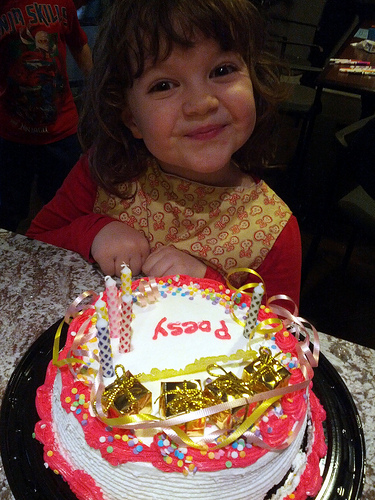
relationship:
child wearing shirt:
[2, 1, 96, 235] [1, 3, 88, 147]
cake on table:
[31, 274, 330, 499] [0, 225, 372, 498]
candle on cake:
[242, 275, 266, 340] [31, 274, 330, 499]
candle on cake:
[119, 290, 134, 350] [31, 274, 330, 499]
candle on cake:
[116, 261, 132, 299] [31, 274, 330, 499]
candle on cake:
[101, 271, 119, 337] [31, 274, 330, 499]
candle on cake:
[95, 316, 113, 378] [31, 274, 330, 499]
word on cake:
[151, 314, 233, 346] [31, 274, 330, 499]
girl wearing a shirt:
[25, 5, 300, 313] [1, 3, 88, 147]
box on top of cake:
[244, 351, 284, 403] [31, 274, 330, 499]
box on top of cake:
[207, 371, 248, 437] [31, 274, 330, 499]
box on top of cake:
[161, 379, 201, 431] [31, 274, 330, 499]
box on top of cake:
[94, 368, 149, 415] [31, 274, 330, 499]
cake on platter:
[31, 274, 330, 499] [1, 318, 368, 499]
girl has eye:
[25, 5, 300, 313] [146, 77, 182, 95]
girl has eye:
[25, 5, 300, 313] [206, 60, 238, 79]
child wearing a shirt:
[2, 1, 96, 235] [1, 3, 88, 147]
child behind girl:
[2, 1, 96, 235] [25, 5, 300, 313]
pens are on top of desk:
[329, 56, 374, 77] [317, 0, 375, 126]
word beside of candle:
[151, 314, 233, 346] [242, 275, 266, 340]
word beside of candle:
[151, 314, 233, 346] [116, 261, 132, 299]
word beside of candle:
[151, 314, 233, 346] [119, 290, 134, 350]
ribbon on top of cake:
[263, 293, 327, 371] [31, 274, 330, 499]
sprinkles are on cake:
[130, 287, 247, 315] [31, 274, 330, 499]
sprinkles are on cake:
[60, 382, 289, 473] [31, 274, 330, 499]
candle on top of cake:
[95, 316, 113, 378] [31, 274, 330, 499]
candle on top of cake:
[119, 290, 134, 350] [31, 274, 330, 499]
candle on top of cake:
[101, 271, 119, 337] [31, 274, 330, 499]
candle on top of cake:
[116, 261, 132, 299] [31, 274, 330, 499]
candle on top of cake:
[242, 275, 266, 340] [31, 274, 330, 499]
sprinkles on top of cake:
[130, 287, 247, 315] [34, 272, 331, 499]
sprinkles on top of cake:
[60, 382, 289, 473] [34, 272, 331, 499]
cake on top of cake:
[34, 272, 331, 499] [31, 274, 330, 499]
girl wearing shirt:
[25, 5, 300, 313] [19, 142, 304, 318]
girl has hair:
[25, 5, 300, 313] [78, 7, 299, 203]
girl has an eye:
[25, 5, 300, 313] [146, 77, 182, 95]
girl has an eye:
[25, 5, 300, 313] [206, 60, 238, 79]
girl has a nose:
[25, 5, 300, 313] [181, 78, 222, 119]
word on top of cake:
[151, 314, 233, 346] [31, 274, 330, 499]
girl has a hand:
[25, 5, 300, 313] [143, 246, 209, 280]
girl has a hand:
[25, 5, 300, 313] [86, 218, 149, 281]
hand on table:
[143, 246, 209, 280] [0, 225, 372, 498]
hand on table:
[86, 218, 149, 281] [0, 225, 372, 498]